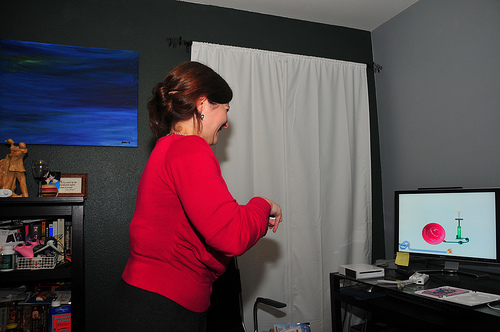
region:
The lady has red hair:
[152, 59, 232, 145]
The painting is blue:
[2, 38, 137, 149]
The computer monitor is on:
[393, 189, 498, 264]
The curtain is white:
[196, 40, 377, 273]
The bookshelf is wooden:
[2, 195, 92, 328]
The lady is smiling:
[151, 57, 236, 149]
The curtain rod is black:
[163, 32, 193, 52]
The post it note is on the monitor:
[392, 249, 412, 268]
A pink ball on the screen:
[418, 221, 448, 245]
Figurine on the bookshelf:
[2, 136, 29, 200]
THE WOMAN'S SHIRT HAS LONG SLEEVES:
[118, 130, 276, 303]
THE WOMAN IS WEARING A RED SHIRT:
[107, 125, 278, 311]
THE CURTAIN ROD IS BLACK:
[163, 24, 396, 81]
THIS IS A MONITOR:
[380, 175, 496, 277]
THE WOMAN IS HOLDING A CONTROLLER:
[257, 202, 288, 242]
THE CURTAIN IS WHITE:
[177, 32, 384, 328]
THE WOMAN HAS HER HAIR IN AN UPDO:
[130, 55, 210, 141]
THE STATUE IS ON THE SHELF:
[0, 128, 32, 200]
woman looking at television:
[118, 40, 494, 329]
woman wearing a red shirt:
[127, 131, 309, 284]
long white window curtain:
[181, 40, 438, 327]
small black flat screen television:
[367, 175, 499, 286]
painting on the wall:
[1, 26, 147, 171]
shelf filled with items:
[1, 187, 93, 329]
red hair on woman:
[143, 73, 241, 120]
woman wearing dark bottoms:
[108, 273, 190, 328]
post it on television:
[397, 238, 417, 267]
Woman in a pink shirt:
[118, 60, 271, 328]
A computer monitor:
[395, 186, 498, 265]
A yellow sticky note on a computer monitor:
[393, 249, 410, 269]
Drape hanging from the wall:
[187, 35, 369, 330]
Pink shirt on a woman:
[123, 132, 260, 310]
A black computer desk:
[331, 268, 497, 327]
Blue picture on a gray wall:
[0, 36, 138, 148]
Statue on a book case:
[0, 135, 29, 199]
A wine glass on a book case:
[30, 160, 47, 196]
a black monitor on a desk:
[394, 185, 499, 267]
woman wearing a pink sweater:
[125, 134, 272, 312]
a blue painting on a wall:
[0, 38, 141, 146]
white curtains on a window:
[188, 39, 371, 329]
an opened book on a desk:
[416, 285, 499, 310]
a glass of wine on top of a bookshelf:
[31, 158, 50, 196]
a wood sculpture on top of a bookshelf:
[0, 137, 27, 197]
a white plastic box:
[17, 255, 60, 269]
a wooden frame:
[58, 173, 86, 197]